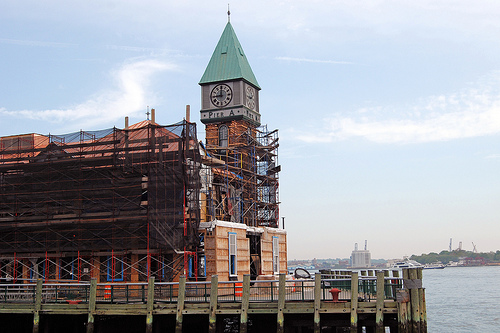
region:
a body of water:
[423, 264, 498, 331]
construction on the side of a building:
[7, 135, 207, 277]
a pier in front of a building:
[2, 259, 419, 331]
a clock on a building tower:
[206, 78, 263, 121]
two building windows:
[225, 229, 293, 276]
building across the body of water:
[298, 234, 488, 278]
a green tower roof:
[197, 15, 269, 90]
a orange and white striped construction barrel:
[227, 278, 249, 303]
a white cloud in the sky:
[327, 69, 499, 173]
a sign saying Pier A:
[194, 104, 259, 124]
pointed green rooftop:
[196, 20, 264, 85]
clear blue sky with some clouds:
[0, 1, 498, 258]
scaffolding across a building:
[3, 103, 280, 260]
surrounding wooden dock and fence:
[1, 260, 436, 326]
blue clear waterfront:
[291, 270, 497, 328]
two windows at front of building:
[227, 233, 278, 274]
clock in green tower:
[205, 80, 235, 105]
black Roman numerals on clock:
[205, 80, 232, 105]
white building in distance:
[346, 236, 369, 263]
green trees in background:
[406, 240, 498, 264]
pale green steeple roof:
[211, 14, 287, 104]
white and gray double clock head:
[197, 83, 275, 111]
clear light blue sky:
[311, 167, 470, 227]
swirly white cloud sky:
[1, 41, 171, 118]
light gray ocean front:
[451, 276, 494, 325]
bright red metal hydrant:
[323, 277, 349, 310]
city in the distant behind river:
[309, 240, 498, 279]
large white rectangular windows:
[223, 232, 244, 282]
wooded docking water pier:
[66, 274, 407, 309]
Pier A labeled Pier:
[204, 110, 244, 125]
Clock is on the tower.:
[186, 45, 273, 142]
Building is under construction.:
[0, 102, 309, 253]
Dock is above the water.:
[18, 267, 464, 329]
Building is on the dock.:
[17, 116, 499, 318]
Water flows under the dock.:
[294, 260, 496, 330]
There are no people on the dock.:
[213, 232, 419, 325]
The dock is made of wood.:
[19, 253, 474, 324]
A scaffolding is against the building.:
[18, 106, 320, 276]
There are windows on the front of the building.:
[209, 219, 291, 283]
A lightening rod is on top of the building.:
[196, 3, 261, 79]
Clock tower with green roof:
[196, 25, 254, 125]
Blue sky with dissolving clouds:
[330, 74, 459, 169]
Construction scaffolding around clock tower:
[195, 13, 276, 225]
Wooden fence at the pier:
[273, 272, 348, 330]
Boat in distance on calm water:
[423, 250, 463, 286]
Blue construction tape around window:
[178, 231, 213, 286]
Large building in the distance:
[339, 237, 383, 273]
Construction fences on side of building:
[28, 130, 167, 183]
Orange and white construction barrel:
[226, 276, 247, 302]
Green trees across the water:
[417, 242, 491, 279]